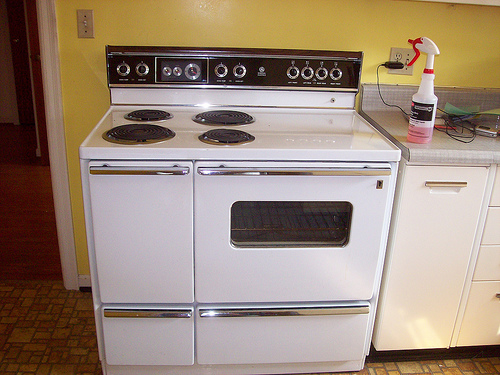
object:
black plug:
[385, 61, 404, 69]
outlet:
[388, 47, 415, 76]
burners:
[101, 109, 256, 146]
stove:
[76, 44, 403, 375]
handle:
[425, 181, 468, 187]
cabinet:
[369, 162, 499, 352]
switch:
[76, 9, 96, 38]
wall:
[56, 2, 499, 94]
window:
[230, 200, 354, 251]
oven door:
[195, 160, 391, 305]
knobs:
[116, 60, 344, 81]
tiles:
[367, 354, 500, 375]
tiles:
[3, 287, 93, 368]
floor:
[0, 166, 57, 280]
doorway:
[35, 0, 86, 292]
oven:
[88, 159, 392, 302]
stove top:
[77, 106, 402, 166]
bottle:
[406, 36, 439, 144]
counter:
[358, 83, 500, 166]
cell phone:
[470, 125, 498, 139]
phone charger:
[375, 61, 479, 144]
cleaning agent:
[407, 125, 433, 144]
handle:
[196, 165, 392, 178]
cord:
[374, 64, 409, 116]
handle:
[89, 165, 190, 177]